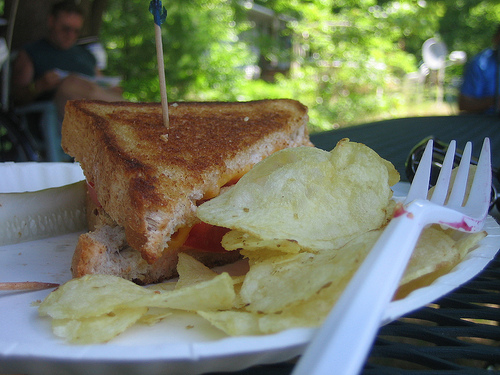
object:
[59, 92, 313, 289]
sandwich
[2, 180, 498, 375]
plate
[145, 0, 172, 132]
toothpick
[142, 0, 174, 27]
frill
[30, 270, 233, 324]
potato chips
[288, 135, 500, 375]
fork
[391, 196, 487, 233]
food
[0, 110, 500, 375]
table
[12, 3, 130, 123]
man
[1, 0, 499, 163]
background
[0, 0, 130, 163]
house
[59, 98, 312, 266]
cheese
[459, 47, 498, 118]
shirt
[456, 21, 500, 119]
man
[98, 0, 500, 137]
foliage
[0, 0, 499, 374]
design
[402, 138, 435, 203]
prongs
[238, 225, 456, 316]
pickle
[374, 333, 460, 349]
holes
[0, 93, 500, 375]
lunch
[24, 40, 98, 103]
shirt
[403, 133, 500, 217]
sunglasses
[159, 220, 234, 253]
sauce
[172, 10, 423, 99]
these